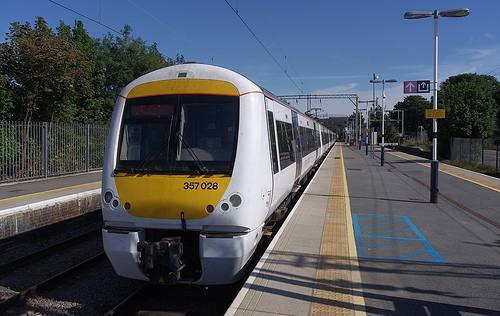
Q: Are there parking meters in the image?
A: No, there are no parking meters.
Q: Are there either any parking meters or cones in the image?
A: No, there are no parking meters or cones.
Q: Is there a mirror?
A: No, there are no mirrors.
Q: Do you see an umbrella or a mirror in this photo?
A: No, there are no mirrors or umbrellas.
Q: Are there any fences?
A: Yes, there is a fence.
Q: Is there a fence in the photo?
A: Yes, there is a fence.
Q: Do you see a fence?
A: Yes, there is a fence.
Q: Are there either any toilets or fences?
A: Yes, there is a fence.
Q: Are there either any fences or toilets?
A: Yes, there is a fence.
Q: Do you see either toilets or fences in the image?
A: Yes, there is a fence.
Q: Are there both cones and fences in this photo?
A: No, there is a fence but no cones.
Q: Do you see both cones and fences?
A: No, there is a fence but no cones.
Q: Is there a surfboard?
A: No, there are no surfboards.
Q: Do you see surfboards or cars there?
A: No, there are no surfboards or cars.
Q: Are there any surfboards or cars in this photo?
A: No, there are no surfboards or cars.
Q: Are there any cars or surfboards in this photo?
A: No, there are no surfboards or cars.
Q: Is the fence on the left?
A: Yes, the fence is on the left of the image.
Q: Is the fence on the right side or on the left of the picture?
A: The fence is on the left of the image.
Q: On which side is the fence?
A: The fence is on the left of the image.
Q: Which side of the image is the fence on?
A: The fence is on the left of the image.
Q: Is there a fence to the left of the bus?
A: Yes, there is a fence to the left of the bus.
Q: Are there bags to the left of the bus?
A: No, there is a fence to the left of the bus.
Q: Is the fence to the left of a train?
A: No, the fence is to the left of the bus.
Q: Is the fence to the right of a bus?
A: No, the fence is to the left of a bus.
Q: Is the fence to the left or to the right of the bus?
A: The fence is to the left of the bus.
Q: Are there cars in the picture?
A: No, there are no cars.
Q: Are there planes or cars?
A: No, there are no cars or planes.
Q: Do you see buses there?
A: Yes, there is a bus.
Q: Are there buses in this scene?
A: Yes, there is a bus.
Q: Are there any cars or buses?
A: Yes, there is a bus.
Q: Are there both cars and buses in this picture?
A: No, there is a bus but no cars.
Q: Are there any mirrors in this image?
A: No, there are no mirrors.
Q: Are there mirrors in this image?
A: No, there are no mirrors.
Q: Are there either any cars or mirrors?
A: No, there are no mirrors or cars.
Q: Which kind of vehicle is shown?
A: The vehicle is a bus.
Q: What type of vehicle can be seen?
A: The vehicle is a bus.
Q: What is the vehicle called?
A: The vehicle is a bus.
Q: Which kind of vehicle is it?
A: The vehicle is a bus.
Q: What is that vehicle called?
A: That is a bus.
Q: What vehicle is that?
A: That is a bus.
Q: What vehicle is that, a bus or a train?
A: That is a bus.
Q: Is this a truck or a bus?
A: This is a bus.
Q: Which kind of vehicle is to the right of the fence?
A: The vehicle is a bus.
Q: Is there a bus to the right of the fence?
A: Yes, there is a bus to the right of the fence.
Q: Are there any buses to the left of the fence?
A: No, the bus is to the right of the fence.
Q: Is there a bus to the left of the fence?
A: No, the bus is to the right of the fence.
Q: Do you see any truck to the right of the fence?
A: No, there is a bus to the right of the fence.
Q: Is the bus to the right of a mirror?
A: No, the bus is to the right of the fence.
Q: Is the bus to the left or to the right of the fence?
A: The bus is to the right of the fence.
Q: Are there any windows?
A: Yes, there are windows.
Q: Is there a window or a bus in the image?
A: Yes, there are windows.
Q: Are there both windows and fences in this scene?
A: Yes, there are both windows and a fence.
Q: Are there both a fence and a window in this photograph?
A: Yes, there are both a window and a fence.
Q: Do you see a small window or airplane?
A: Yes, there are small windows.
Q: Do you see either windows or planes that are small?
A: Yes, the windows are small.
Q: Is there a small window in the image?
A: Yes, there are small windows.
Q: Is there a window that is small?
A: Yes, there are windows that are small.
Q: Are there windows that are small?
A: Yes, there are windows that are small.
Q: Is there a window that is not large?
A: Yes, there are small windows.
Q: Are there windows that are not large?
A: Yes, there are small windows.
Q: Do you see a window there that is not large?
A: Yes, there are small windows.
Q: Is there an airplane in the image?
A: No, there are no airplanes.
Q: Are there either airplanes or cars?
A: No, there are no airplanes or cars.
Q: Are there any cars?
A: No, there are no cars.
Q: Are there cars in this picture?
A: No, there are no cars.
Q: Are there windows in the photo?
A: Yes, there are windows.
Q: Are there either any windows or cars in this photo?
A: Yes, there are windows.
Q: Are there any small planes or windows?
A: Yes, there are small windows.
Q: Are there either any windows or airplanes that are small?
A: Yes, the windows are small.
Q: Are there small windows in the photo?
A: Yes, there are small windows.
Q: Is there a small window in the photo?
A: Yes, there are small windows.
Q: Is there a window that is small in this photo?
A: Yes, there are small windows.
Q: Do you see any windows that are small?
A: Yes, there are windows that are small.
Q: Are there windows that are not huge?
A: Yes, there are small windows.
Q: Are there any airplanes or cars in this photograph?
A: No, there are no cars or airplanes.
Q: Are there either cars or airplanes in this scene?
A: No, there are no cars or airplanes.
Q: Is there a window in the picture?
A: Yes, there are windows.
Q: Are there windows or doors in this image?
A: Yes, there are windows.